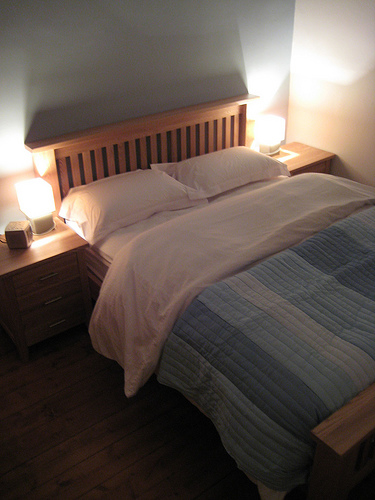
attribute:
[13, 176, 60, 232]
light — white, on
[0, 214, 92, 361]
nightstand — light, wood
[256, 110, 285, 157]
light — white, on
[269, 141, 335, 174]
nightstand — light, wood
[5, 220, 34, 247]
clock — bedside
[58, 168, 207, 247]
pillow — white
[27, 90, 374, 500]
bed — properly made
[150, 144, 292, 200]
pillow — white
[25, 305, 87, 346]
drawer — closed, wood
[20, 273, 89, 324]
drawer — closed, wood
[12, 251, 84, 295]
drawer — closed, wood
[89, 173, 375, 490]
comforter — blue, striped, turned down, quilted, white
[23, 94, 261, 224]
headboard — wooden, slatted, wood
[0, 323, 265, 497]
floor — hardwood, wooden, clean, brown, wood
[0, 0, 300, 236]
wall — blue, light blue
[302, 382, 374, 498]
footboard — wooden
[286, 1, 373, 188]
wall — white